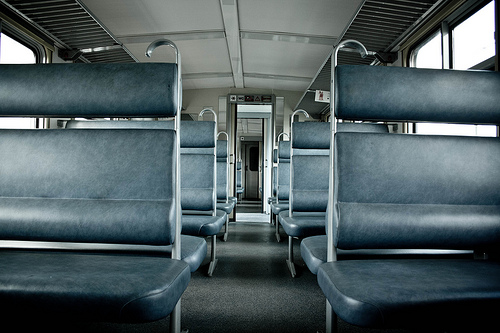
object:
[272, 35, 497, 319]
seating area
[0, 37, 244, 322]
seating area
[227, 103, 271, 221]
door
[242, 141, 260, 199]
door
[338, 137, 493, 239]
leather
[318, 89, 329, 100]
sign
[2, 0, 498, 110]
ceiling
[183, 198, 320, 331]
walk-way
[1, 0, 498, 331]
train car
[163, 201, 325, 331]
floor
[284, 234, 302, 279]
leg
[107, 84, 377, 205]
wall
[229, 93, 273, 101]
sign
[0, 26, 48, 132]
window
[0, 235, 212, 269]
seat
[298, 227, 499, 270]
seat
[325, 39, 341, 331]
curve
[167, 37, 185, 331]
curve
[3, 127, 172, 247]
backrest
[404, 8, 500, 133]
glass window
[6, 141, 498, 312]
area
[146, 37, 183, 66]
hook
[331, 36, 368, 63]
hook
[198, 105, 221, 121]
hook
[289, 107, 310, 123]
hook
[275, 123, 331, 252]
seat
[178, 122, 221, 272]
seat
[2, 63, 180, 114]
rest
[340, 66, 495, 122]
rest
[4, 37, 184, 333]
seat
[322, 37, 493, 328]
seat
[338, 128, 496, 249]
backrest